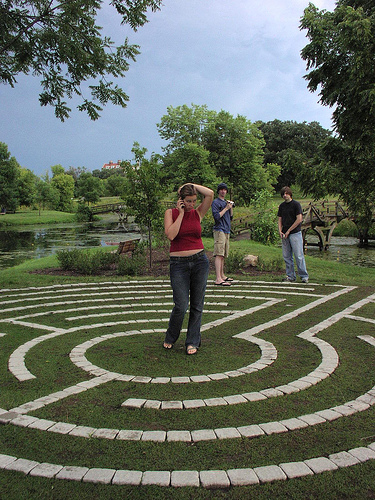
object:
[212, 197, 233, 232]
shirt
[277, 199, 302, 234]
tshirt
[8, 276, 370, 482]
sundial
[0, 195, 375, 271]
pond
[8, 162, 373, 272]
park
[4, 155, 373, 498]
another part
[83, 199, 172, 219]
briddge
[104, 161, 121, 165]
roof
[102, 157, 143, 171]
house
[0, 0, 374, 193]
background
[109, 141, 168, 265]
trees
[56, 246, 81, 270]
shrubs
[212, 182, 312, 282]
men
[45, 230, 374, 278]
edge of maze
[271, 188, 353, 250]
structure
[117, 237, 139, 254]
bench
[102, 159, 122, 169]
building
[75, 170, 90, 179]
treetops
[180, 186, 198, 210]
head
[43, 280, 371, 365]
maze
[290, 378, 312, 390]
squarestones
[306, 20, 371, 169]
tree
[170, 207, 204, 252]
top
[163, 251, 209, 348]
jeans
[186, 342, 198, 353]
sandals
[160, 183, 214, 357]
girl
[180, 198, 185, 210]
cellphone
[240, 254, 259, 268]
flat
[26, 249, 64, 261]
on grass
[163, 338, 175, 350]
summer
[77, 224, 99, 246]
water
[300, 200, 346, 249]
bench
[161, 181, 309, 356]
people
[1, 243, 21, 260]
water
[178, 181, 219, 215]
arm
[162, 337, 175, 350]
flipflops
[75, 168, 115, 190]
hill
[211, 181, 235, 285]
guy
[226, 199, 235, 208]
camera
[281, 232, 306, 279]
jeans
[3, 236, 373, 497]
ground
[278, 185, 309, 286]
guy